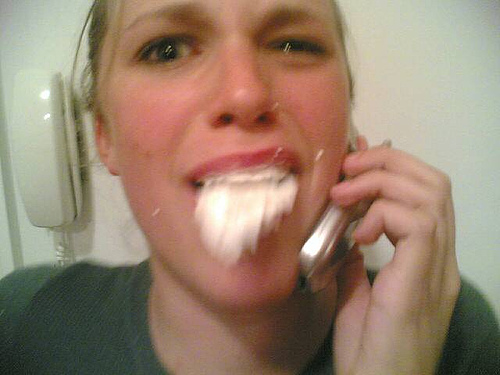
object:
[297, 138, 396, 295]
silver phone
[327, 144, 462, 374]
left hand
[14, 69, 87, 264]
phone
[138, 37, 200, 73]
eye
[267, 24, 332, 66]
eye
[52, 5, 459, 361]
woman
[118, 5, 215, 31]
eyebrow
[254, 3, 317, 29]
eyebrow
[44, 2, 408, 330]
woman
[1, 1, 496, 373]
woman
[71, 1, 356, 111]
hair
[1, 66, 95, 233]
phone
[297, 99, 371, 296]
cellphone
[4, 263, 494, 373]
shirt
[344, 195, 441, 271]
pinky finger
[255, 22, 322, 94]
eye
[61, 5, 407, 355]
person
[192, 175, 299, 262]
foam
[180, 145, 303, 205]
mouth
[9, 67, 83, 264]
phone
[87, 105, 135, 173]
ear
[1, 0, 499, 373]
girl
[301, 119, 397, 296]
phone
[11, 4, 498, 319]
white background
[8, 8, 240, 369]
photo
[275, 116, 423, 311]
cellphone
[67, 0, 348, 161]
hair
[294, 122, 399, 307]
cellphone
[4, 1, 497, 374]
photo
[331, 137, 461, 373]
hand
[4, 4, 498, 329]
wall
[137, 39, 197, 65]
eye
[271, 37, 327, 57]
eye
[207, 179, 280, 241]
stuff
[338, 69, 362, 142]
ear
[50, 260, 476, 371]
shirt